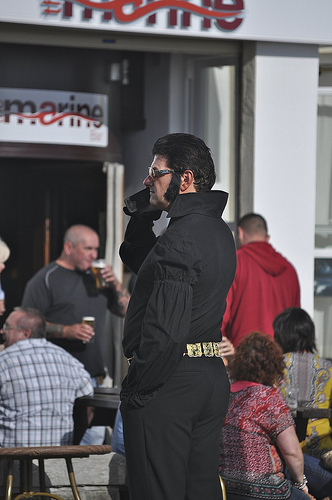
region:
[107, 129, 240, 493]
man dressed as an Elvis impersonator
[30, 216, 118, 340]
man holding two beers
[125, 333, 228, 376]
gold and black belt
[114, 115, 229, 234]
man holding black cell phone to ear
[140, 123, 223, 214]
man with long black side burns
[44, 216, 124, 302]
man taking a sip of beer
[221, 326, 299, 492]
woman in red shirt sitting down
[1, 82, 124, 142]
sign above doorway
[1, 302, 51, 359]
man wearing eye glasses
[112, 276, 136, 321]
tattoos on man's forearms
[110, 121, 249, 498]
person dress as Elvis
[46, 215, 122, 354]
man drinking beer out of glass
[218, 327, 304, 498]
lady in red print shirt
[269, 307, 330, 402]
lady wearing yellow print top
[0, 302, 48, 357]
man wearing glasses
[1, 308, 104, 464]
man wearing blue plaid shirt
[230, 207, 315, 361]
young adult wearing red hoodie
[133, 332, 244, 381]
gold plated belt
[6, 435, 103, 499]
wooden top table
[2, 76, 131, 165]
red and white signage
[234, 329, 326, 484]
Woman with brown hair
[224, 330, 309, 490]
Woman with curly brown hair and red shirt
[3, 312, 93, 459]
Man with glasses in a plaid blue shirt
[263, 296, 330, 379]
Woman with brown hair in a yellow and black shirt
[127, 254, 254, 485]
Black cover alls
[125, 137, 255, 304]
Man in black cover alls talking on a phone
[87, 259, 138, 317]
Glass of beer in a man's hand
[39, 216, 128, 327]
Man in a gray shirt with a bald head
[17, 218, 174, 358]
Man holding two beers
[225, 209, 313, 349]
Man in a red hoodie sweat shirt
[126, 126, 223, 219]
man with exaggerated sideburns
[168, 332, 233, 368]
a fancy golden belt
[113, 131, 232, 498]
a probable Elvis impersonator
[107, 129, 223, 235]
man on a huge cell phone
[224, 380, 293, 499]
a patterned top on a woman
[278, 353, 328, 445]
a patterned top on a woman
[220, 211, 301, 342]
man with a red hoodie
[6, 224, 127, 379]
man sipping beer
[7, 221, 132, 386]
man holding a beer in his right hand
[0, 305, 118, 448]
man sitting in a chair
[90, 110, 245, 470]
man with dark hair and long sideburns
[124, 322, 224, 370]
gold belt of small medallions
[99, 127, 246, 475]
man wearing black jumpsuit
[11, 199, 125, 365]
man holding two glasses of beer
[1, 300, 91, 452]
man wearing plaid shirt in blues and greys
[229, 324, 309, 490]
woman with curly hair seated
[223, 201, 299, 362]
man standing wearing red hooded sweatshirt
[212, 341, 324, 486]
shirts with busy prints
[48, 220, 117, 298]
man sipping from a glass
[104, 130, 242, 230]
man holding phone to ear